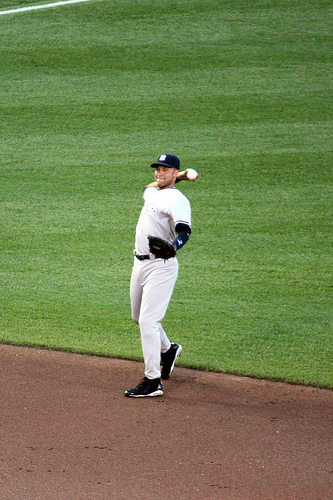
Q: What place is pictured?
A: It is a field.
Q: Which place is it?
A: It is a field.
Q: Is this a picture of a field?
A: Yes, it is showing a field.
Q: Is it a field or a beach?
A: It is a field.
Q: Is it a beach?
A: No, it is a field.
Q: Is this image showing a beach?
A: No, the picture is showing a field.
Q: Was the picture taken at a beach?
A: No, the picture was taken in a field.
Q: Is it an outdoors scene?
A: Yes, it is outdoors.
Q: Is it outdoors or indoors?
A: It is outdoors.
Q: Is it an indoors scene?
A: No, it is outdoors.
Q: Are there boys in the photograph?
A: No, there are no boys.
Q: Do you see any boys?
A: No, there are no boys.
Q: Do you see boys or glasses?
A: No, there are no boys or glasses.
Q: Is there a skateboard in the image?
A: No, there are no skateboards.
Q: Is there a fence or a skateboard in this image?
A: No, there are no skateboards or fences.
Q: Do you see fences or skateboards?
A: No, there are no skateboards or fences.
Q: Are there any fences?
A: No, there are no fences.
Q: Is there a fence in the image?
A: No, there are no fences.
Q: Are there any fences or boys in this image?
A: No, there are no fences or boys.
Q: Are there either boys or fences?
A: No, there are no fences or boys.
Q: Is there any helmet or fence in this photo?
A: No, there are no fences or helmets.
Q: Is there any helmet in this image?
A: No, there are no helmets.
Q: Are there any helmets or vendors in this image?
A: No, there are no helmets or vendors.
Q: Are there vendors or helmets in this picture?
A: No, there are no helmets or vendors.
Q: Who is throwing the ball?
A: The man is throwing the ball.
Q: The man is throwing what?
A: The man is throwing the ball.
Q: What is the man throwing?
A: The man is throwing the ball.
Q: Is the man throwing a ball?
A: Yes, the man is throwing a ball.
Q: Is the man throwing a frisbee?
A: No, the man is throwing a ball.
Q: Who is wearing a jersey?
A: The man is wearing a jersey.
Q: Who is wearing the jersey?
A: The man is wearing a jersey.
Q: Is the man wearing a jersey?
A: Yes, the man is wearing a jersey.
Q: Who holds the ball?
A: The man holds the ball.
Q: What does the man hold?
A: The man holds the ball.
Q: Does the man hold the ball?
A: Yes, the man holds the ball.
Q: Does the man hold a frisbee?
A: No, the man holds the ball.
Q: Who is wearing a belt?
A: The man is wearing a belt.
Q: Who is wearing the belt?
A: The man is wearing a belt.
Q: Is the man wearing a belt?
A: Yes, the man is wearing a belt.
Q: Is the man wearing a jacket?
A: No, the man is wearing a belt.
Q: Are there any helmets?
A: No, there are no helmets.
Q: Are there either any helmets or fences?
A: No, there are no helmets or fences.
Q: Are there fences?
A: No, there are no fences.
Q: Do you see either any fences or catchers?
A: No, there are no fences or catchers.